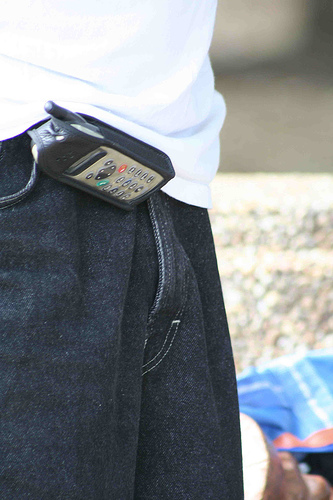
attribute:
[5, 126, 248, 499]
pants — dark, denim, dark wash, blue, pair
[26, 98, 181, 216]
phone — gray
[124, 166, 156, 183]
buttons — red, green, black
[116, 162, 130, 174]
button — red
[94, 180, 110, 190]
button — green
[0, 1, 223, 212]
shirt — white, untucked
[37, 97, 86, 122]
antenna — black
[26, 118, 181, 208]
case — leather, black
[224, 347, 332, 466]
something — blue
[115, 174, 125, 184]
button — black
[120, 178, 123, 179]
letters — white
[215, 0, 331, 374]
background — blurry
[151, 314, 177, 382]
seams — white, double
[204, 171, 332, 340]
sand — gray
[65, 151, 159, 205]
front — clear